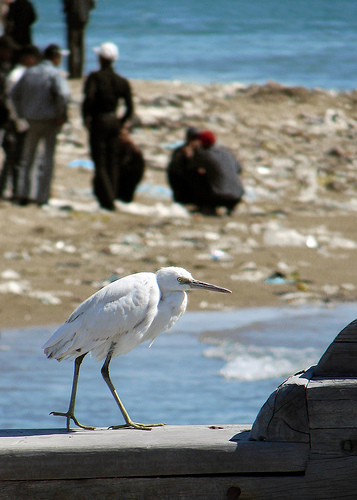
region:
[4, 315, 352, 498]
a wooden fence before the water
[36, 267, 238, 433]
a white bird on the wall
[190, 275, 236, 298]
the bird has a beak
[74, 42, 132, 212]
a person on the beach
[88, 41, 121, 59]
he has a white baseball cap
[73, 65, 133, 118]
his shirt is black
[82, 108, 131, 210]
his pants are black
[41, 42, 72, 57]
he is wearing a cap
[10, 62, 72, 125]
his shirt is grey-black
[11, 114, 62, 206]
his pants are grey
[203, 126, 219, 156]
Person wearing red hat.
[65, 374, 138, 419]
Bird has gray legs.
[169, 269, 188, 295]
Bird has yellow eye.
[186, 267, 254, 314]
Bird has gray beak.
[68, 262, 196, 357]
Bird has white feathers.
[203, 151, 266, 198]
Person wearing gray shirt.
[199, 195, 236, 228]
Person wearing black pants.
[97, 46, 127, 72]
Person wearing white hat.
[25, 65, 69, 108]
Person wearing blue jacket.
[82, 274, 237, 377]
the seagull is white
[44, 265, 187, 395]
the bird is white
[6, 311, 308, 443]
the water is blue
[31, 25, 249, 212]
people in the background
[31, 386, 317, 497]
the bird stands on wood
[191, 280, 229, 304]
bird has a long beak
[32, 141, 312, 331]
people standing on sand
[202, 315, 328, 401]
the water makes a little wave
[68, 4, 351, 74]
water in the background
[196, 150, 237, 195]
his shirt is black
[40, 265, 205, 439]
white bird on wall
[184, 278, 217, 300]
bird has grey beak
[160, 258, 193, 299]
bird has white head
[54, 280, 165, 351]
bird has white body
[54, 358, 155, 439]
bird has green legs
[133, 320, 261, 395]
water is bright blue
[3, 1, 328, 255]
people standing on beach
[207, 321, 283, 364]
small waves on water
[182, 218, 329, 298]
ground is light brown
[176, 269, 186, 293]
bird has small yellow eyes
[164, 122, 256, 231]
people squatting on the river bank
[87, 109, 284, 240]
people squatting on the river bank